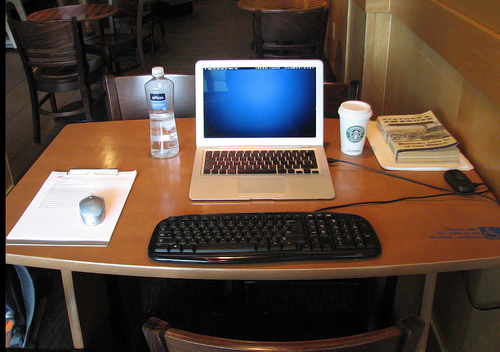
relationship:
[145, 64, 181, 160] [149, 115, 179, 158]
bottle of water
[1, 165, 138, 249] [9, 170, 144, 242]
clipboard holds paper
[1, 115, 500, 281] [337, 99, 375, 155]
table in starbucks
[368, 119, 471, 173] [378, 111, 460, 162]
papers and a book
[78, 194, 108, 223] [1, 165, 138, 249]
mouse on a clipboard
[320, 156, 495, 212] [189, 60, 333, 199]
wires for laptop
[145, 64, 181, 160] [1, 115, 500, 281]
bottle on table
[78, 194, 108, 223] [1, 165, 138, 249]
mouse on clipboard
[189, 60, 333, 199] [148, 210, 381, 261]
laptop and keyboard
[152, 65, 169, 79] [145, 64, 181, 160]
cap on bottle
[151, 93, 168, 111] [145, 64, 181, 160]
lable on bottle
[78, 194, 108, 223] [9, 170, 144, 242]
mouse on paper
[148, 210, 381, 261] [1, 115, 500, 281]
keyboard on table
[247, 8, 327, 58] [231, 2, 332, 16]
chair near a table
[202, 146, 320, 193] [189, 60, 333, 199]
keyboard of laptop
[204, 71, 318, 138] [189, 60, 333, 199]
screen of laptop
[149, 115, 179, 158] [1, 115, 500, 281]
water on table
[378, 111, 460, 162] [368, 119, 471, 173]
book on paper